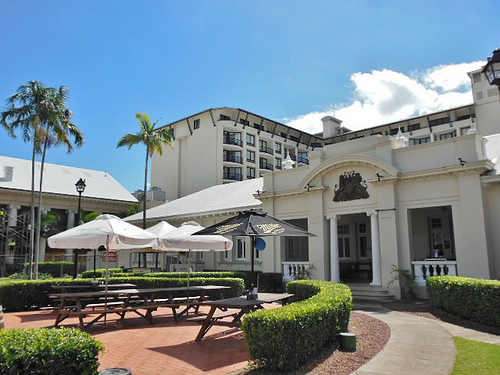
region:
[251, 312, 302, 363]
well-trimmed hedge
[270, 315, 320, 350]
the leaves are green in color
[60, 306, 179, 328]
this is a wooden bench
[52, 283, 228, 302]
these are wooden tables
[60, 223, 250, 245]
these are open umbrellas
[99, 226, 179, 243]
the umbrellas are white in color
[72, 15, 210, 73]
this is the sky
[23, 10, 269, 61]
the sky is blue in color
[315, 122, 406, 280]
this is a tall building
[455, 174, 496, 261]
the walls are white in color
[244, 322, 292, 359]
this is a hedge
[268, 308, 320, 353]
the hedge is well-trimmed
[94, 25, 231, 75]
the sky is blue in color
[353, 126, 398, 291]
this is a tall building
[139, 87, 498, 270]
this is a building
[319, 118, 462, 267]
the building is white in color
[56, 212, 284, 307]
a shade is outside the building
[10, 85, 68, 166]
the palm tree is tall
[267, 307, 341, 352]
the fence is well trimmed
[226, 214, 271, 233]
the umbrella is back in color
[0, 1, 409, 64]
the sky is blue in color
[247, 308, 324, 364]
the fence is green in color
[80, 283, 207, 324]
the benches are empty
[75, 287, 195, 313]
the benches are wooden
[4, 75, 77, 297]
green palms on a palm tree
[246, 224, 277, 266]
blue balloon hanging under umbrella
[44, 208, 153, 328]
picnic table with white umbrella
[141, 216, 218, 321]
picnic table with white umbrella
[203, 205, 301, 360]
picnic table with black umbrella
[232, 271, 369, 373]
green shrub along sidewalk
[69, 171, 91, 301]
street lamp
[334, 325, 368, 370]
gray trash can on sidewak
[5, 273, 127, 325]
green shrub divider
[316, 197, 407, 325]
two white columns at building entrance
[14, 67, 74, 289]
tall green palm tree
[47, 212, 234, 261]
three white umbrellas over wooden tables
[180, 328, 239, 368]
shadow cast by table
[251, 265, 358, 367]
well manicured green bush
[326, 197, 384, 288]
two white columns at front of building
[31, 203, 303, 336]
set of picnic tables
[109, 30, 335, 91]
clear blue sky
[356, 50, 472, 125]
bright white clouds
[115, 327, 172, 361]
red brick in picnic area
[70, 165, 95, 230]
old fashioned lamp post